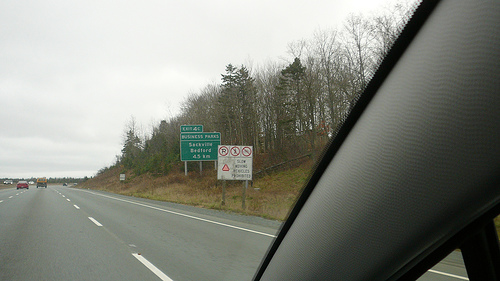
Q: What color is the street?
A: Gray.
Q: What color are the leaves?
A: Green.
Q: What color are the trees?
A: Brown.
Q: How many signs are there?
A: 3.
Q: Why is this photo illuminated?
A: Sunlight.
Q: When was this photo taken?
A: During the day.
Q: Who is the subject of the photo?
A: The highway.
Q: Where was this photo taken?
A: On a highway.